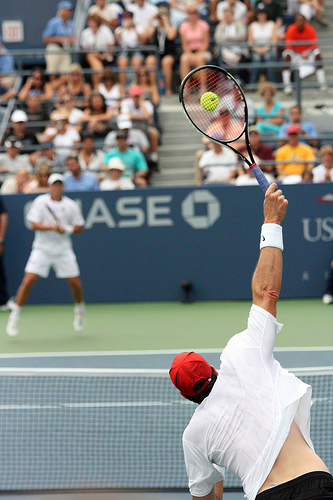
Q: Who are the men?
A: Tennis players.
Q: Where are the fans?
A: The stands.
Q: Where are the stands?
A: Behind court.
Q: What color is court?
A: Green.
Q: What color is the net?
A: Black.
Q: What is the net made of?
A: String.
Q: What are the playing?
A: Tennis.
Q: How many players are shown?
A: Two.